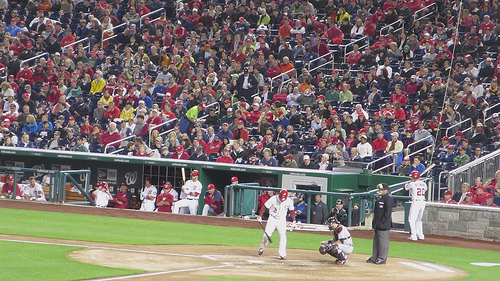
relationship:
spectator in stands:
[103, 102, 118, 117] [2, 7, 490, 159]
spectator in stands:
[281, 56, 295, 71] [2, 7, 490, 159]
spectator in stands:
[218, 124, 230, 143] [2, 7, 490, 159]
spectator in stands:
[357, 137, 373, 158] [2, 7, 490, 159]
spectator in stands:
[62, 29, 77, 47] [2, 7, 490, 159]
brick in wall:
[440, 210, 460, 224] [404, 204, 498, 236]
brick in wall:
[450, 221, 470, 233] [404, 204, 498, 236]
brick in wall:
[462, 213, 477, 221] [404, 204, 498, 236]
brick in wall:
[466, 223, 481, 231] [404, 204, 498, 236]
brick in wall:
[485, 228, 500, 238] [404, 204, 498, 236]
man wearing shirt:
[122, 100, 135, 122] [122, 111, 132, 121]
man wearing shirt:
[89, 70, 107, 98] [88, 80, 104, 93]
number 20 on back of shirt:
[415, 187, 426, 199] [409, 181, 430, 203]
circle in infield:
[70, 236, 459, 280] [0, 209, 494, 277]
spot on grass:
[473, 259, 500, 269] [406, 235, 497, 279]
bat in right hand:
[258, 225, 275, 245] [254, 215, 264, 222]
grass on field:
[5, 225, 234, 276] [0, 209, 494, 277]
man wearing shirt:
[327, 85, 341, 105] [326, 93, 337, 102]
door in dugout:
[279, 177, 328, 222] [0, 150, 387, 226]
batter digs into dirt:
[255, 192, 291, 259] [252, 250, 295, 272]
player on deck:
[404, 167, 433, 243] [388, 227, 488, 259]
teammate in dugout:
[92, 182, 115, 205] [0, 150, 387, 226]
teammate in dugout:
[116, 187, 133, 209] [0, 150, 387, 226]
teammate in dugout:
[138, 177, 158, 212] [0, 150, 387, 226]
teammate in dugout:
[176, 168, 205, 217] [0, 150, 387, 226]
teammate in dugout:
[22, 173, 43, 199] [0, 150, 387, 226]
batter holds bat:
[255, 192, 291, 259] [258, 225, 275, 245]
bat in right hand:
[258, 225, 275, 245] [254, 215, 263, 222]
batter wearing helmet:
[255, 192, 291, 259] [280, 192, 289, 204]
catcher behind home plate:
[322, 217, 355, 264] [245, 258, 265, 265]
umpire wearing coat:
[372, 185, 398, 265] [375, 197, 391, 231]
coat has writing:
[375, 197, 391, 231] [378, 201, 386, 210]